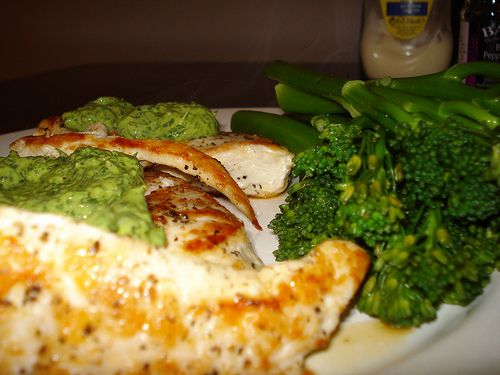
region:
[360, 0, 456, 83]
a half full condiment bottle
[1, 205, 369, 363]
a lightly seared piece of meat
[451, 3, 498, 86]
a bottle with a dark label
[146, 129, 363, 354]
a few pieces of chicken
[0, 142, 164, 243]
a thick green sauce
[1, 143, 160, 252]
a puree of avocado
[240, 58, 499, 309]
a pile of broccolini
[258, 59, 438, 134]
a few green stems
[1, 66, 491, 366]
a health conscious lunch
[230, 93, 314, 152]
this is a vegetable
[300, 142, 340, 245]
this is a vegetable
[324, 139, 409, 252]
this is a vegetable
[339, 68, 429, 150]
this is a vegetable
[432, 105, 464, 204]
this is a vegetable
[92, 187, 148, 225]
this is mashed avocado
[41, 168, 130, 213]
this is mashed avocado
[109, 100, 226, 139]
this is mashed avocado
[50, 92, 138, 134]
this is mashed avocado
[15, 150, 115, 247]
green sauce on plate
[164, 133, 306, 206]
white chicken on plate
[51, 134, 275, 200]
orange crust on chicken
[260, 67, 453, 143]
haricots verts on plate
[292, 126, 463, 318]
green broccoli on plate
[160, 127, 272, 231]
chicken has black pepper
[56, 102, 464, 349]
white and oval plate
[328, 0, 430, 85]
white sauce in bottle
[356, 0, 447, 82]
bottle is behind plate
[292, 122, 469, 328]
dark green cooked broccoli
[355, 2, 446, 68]
a bottle on the table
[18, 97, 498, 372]
a plate on the table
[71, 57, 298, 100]
the table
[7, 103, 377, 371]
chicken on the plate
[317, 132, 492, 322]
the leaves of the asparagus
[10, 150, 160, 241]
green sauce on the chicken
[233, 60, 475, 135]
stems on the asparagus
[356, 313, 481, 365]
the edge of the white plate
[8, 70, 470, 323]
a plate of food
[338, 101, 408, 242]
A piece of food.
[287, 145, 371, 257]
A piece of food.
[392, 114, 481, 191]
A piece of food.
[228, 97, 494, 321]
A piece of food.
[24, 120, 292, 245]
A piece of food.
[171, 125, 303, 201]
A piece of food.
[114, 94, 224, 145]
A piece of food.